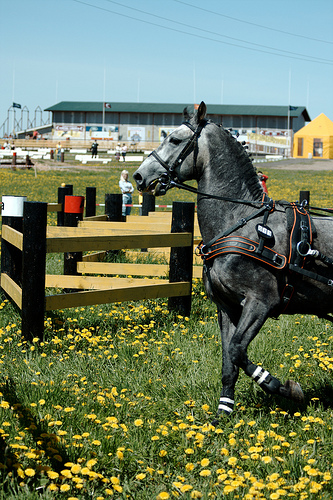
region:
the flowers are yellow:
[67, 415, 311, 488]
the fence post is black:
[9, 188, 59, 349]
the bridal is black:
[159, 154, 202, 175]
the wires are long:
[152, 1, 331, 65]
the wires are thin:
[175, 11, 274, 49]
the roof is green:
[116, 101, 159, 113]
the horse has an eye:
[163, 133, 185, 144]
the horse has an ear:
[166, 97, 218, 119]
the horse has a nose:
[122, 164, 151, 189]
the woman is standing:
[105, 159, 134, 196]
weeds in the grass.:
[72, 332, 99, 352]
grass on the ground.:
[193, 357, 210, 382]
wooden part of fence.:
[76, 229, 147, 252]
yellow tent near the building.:
[308, 115, 324, 130]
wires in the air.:
[170, 9, 201, 37]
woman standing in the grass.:
[121, 170, 134, 201]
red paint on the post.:
[62, 197, 82, 210]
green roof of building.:
[217, 107, 264, 109]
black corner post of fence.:
[27, 205, 38, 318]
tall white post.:
[192, 67, 196, 99]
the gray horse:
[107, 112, 332, 398]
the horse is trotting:
[121, 107, 332, 405]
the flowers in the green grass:
[67, 317, 154, 361]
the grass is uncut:
[70, 329, 171, 434]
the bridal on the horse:
[150, 119, 271, 214]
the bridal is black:
[150, 114, 217, 214]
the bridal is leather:
[145, 123, 226, 189]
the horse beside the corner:
[6, 192, 199, 315]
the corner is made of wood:
[0, 191, 208, 337]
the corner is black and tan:
[3, 184, 199, 324]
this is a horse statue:
[137, 101, 328, 412]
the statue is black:
[127, 100, 332, 417]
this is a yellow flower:
[179, 443, 194, 458]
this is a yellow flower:
[134, 419, 146, 429]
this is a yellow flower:
[134, 470, 146, 484]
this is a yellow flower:
[108, 481, 125, 497]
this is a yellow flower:
[45, 468, 57, 481]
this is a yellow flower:
[71, 463, 83, 474]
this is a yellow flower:
[155, 486, 166, 498]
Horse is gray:
[131, 96, 331, 428]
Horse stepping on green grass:
[131, 100, 331, 422]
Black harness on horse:
[149, 122, 272, 213]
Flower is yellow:
[200, 457, 209, 466]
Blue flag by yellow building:
[286, 102, 297, 126]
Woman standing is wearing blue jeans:
[118, 165, 135, 211]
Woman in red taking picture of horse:
[256, 169, 272, 192]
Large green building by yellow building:
[40, 100, 310, 157]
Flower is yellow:
[82, 428, 90, 437]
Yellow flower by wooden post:
[32, 334, 39, 342]